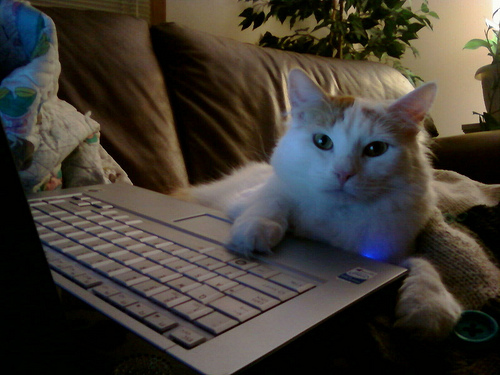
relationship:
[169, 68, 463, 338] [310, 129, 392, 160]
cat has eyes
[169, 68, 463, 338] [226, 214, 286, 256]
cat has paw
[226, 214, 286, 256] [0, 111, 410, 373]
paw on laptop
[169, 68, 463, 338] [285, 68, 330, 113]
cat has ear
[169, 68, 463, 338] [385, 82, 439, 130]
cat has ear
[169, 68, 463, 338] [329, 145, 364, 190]
cat has nose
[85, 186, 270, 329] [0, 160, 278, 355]
keyboard on laptop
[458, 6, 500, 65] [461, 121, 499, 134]
plant on table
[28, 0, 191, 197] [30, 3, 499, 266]
couch cushions on brown couch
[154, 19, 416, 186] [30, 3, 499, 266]
cushion on brown couch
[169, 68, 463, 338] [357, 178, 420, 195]
cat has whiskers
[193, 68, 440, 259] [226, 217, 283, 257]
cat has paw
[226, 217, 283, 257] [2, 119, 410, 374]
paw on computer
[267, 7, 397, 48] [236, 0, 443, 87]
leaves on plant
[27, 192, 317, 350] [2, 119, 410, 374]
keyboard on computer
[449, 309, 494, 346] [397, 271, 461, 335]
soda lid by cat's paw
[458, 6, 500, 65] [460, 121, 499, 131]
plant on table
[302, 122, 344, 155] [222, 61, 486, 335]
eye on cat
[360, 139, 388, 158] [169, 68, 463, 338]
eye on cat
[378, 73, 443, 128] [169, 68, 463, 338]
ear on cat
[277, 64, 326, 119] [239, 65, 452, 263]
ear on cat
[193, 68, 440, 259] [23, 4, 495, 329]
cat on couch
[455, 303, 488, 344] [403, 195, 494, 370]
button on sweater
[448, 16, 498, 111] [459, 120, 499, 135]
plant on table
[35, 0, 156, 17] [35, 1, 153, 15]
blinds on blinds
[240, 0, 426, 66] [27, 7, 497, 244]
plant behind couch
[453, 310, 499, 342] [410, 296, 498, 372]
button on sweater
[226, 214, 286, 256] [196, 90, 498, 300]
paw of cat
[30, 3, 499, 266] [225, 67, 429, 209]
brown couch under cat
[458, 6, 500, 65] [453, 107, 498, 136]
plant on table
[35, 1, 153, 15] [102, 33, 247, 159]
blinds in window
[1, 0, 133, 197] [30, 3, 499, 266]
blanket on brown couch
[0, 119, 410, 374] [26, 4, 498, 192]
computer on couch